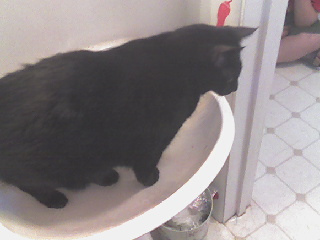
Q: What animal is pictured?
A: A cat.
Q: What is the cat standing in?
A: The sink.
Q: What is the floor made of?
A: Tile.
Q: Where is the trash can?
A: Under the sink.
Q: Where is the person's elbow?
A: Resting near the person's knee.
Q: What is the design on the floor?
A: Squares.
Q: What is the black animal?
A: A cat.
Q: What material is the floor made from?
A: Tiles.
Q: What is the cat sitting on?
A: A sink.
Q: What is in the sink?
A: A cat.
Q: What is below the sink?
A: Trash Can.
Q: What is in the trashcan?
A: A bag.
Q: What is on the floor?
A: A trashcan.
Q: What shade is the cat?
A: Black.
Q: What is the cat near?
A: Wall.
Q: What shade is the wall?
A: White.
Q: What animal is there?
A: Cat.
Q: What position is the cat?
A: Standing.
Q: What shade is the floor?
A: White.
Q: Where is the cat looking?
A: Floor.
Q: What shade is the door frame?
A: Gray.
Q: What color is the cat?
A: Black.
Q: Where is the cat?
A: In the sink.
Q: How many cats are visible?
A: 1.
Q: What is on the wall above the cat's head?
A: Chili.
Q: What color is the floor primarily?
A: White.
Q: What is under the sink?
A: Trash.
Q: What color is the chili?
A: Red.